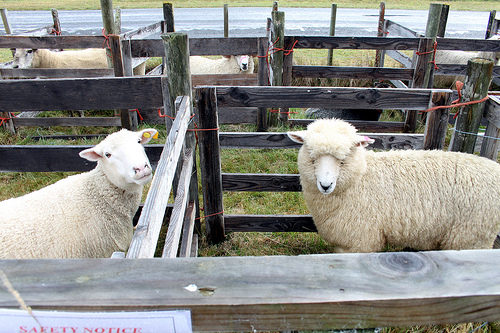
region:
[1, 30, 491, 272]
Four sheep are in the picture.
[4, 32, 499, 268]
The sheep are white.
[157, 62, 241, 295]
A wooden fence is keeping them apart.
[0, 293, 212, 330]
A sign is on the fence.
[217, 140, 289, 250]
Grass is growing in the pen.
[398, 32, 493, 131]
Red string is holding the fence together.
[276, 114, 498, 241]
The sheep is big.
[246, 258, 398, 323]
The wood is gray and brown.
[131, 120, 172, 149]
The sheep has a yellow tag.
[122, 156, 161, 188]
The sheep has a pink nose.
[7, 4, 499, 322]
A large sheep pin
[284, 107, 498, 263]
A fluffy sheep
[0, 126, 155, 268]
a recently cut sheep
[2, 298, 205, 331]
A safety notice on the pin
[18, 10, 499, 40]
A body of water behind the pin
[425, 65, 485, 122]
orange twine keeping the door closed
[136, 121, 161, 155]
yellow tag on the sheep's ear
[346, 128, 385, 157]
pink tag on the sheep's ear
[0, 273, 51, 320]
twine holding the safety notice up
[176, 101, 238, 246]
orange twine holding the pin together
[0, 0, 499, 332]
an outdoor picture of sheep in a pen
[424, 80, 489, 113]
the gate is secured with a red robe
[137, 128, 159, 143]
the sheep's ears are tagged for identification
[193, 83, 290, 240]
the pens gates are made of wood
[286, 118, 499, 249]
a sheep waiting to be sheared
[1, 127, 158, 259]
a sheep after getting sheared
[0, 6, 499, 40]
a river behind the sheep pens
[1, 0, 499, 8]
green grass in the field behind the river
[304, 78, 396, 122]
a black sheep behind the gate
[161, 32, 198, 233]
wooden support poles for the pens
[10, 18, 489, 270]
five white sheep in pens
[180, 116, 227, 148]
red rope holding pens closed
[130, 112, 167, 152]
yellow tag in sheeps ear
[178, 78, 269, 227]
wooden posts and slats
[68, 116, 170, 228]
sheep looking directly at camera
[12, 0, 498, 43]
road behind sheep pens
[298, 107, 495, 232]
sheep with white wool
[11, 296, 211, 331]
sign attached to wooden pens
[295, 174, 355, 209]
sheep with black nose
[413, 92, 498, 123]
pen door held closed with red rope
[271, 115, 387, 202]
animal with a hairdo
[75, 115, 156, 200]
animal looking at camera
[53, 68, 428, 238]
two animals looking towards camera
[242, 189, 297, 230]
green grass on ground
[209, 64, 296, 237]
gray fence next to animals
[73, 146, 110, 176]
ear of the animal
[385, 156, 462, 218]
white fur of animal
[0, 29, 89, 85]
animal in background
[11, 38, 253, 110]
two animals in the background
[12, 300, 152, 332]
white sign in foreground